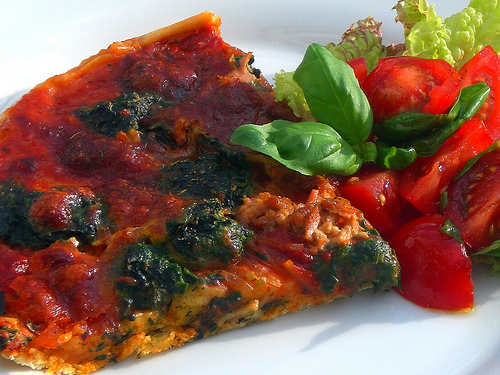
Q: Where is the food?
A: On plate.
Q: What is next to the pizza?
A: A salad.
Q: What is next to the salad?
A: A pizza.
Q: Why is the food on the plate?
A: To be eaten.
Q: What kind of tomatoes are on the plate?
A: Cherry tomatoes.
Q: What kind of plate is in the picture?
A: Porcelain.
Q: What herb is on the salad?
A: Basil.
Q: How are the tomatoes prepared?
A: Sliced.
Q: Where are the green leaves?
A: On the food.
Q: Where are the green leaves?
A: On the tomatoes.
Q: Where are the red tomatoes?
A: The green leaves.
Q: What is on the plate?
A: A quiche.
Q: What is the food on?
A: A white plate.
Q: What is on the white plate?
A: Red tomatoes.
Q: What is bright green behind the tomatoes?
A: Lettuce.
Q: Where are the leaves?
A: Between the quiche and the tomatoes.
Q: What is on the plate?
A: A slice of pizza.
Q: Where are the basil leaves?
A: On the food.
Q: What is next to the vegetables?
A: A slice of pizza.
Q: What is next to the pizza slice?
A: Vegetables.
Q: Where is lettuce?
A: Behind tomatoes.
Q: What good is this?
A: Fresh vegetables and a slice of pizza.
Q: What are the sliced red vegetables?
A: Tomatoes.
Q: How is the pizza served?
A: Sliced.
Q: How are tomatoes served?
A: Sliced.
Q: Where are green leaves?
A: On tomatoes.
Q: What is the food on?
A: White surface.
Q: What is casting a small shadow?
A: Vegetables.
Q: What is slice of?
A: Pizza.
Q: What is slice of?
A: Pizza.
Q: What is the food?
A: Pizza.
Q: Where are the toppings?
A: On pizza.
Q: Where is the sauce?
A: On pizza.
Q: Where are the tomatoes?
A: In salad.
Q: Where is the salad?
A: By pizza.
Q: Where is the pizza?
A: On plate.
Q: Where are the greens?
A: On plate.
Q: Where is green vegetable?
A: On pizza.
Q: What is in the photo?
A: Food.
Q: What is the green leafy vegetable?
A: Spinach.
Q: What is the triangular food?
A: Pizza.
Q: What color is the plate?
A: White.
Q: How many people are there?
A: Zero.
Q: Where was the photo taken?
A: Kitchen.